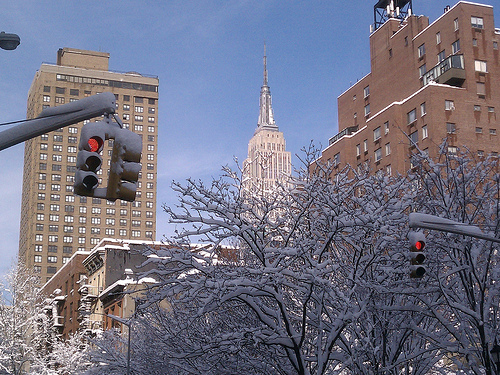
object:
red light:
[88, 135, 105, 153]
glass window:
[435, 46, 467, 70]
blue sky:
[0, 0, 120, 28]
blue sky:
[157, 0, 356, 50]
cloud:
[155, 146, 241, 181]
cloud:
[0, 105, 23, 295]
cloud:
[168, 2, 237, 37]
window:
[373, 146, 382, 162]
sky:
[0, 1, 489, 226]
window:
[368, 123, 384, 143]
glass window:
[380, 149, 388, 158]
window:
[404, 106, 416, 126]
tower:
[239, 40, 298, 230]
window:
[33, 223, 45, 233]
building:
[19, 43, 152, 283]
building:
[309, 0, 499, 191]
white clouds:
[238, 6, 311, 30]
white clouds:
[162, 31, 236, 70]